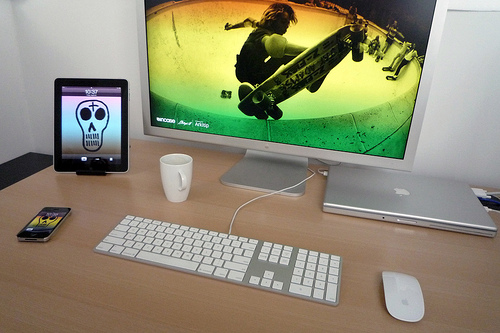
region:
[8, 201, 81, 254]
Phone on the desk.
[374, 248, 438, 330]
The mouse is white.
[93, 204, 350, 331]
The keys are white.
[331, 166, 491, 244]
The laptop is closed.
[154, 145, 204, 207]
Cup on the desk.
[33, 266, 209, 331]
The desk is brown.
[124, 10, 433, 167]
The monitor is on.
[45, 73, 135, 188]
Tablet on a stand.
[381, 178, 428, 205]
Apple logo on the laptop.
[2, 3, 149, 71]
The wall is white.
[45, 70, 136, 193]
An Apple iPad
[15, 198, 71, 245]
an iPhone with a drawing of a skull on the lock screen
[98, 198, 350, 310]
an Apple keyboard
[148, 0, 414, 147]
a man jumping a skateboard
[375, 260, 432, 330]
a white wireless Apple mouse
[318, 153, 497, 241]
a silver Apple laptop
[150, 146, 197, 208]
an empty white coffee cup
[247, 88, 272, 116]
the rubber wheel on a skateboard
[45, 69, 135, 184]
an iPad with a drawing of a skull on the locked screen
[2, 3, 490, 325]
a desk with several Apple products on it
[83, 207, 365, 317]
a white computer keyboard on a desk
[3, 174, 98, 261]
a cell phone on a desk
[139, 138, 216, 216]
a white coffee cup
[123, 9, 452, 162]
a silver computer monitor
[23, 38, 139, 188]
a computer tablet on a stand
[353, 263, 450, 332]
a white computer mouse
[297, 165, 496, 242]
a silver laptop on a desk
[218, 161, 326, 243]
a white cord attached to keyboard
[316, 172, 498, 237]
a closed laptop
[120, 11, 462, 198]
a computer monitor on a stand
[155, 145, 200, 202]
white ceramic coffee mug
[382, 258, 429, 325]
white computer mouse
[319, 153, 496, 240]
silver Apple laptop closed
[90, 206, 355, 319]
white and grey computer keyboard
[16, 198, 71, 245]
cell phone with skull on wallpaper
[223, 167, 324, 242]
keyboard cord snaking around monitor base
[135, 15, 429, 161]
computer monitor turned on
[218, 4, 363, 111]
skateboard graphic on monitor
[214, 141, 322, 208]
silver monitor base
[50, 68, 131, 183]
Ipad with skull on front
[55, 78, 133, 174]
Tablet on wooden table.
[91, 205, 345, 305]
Keyboard on wooden table.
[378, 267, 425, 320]
White computer mouse on wooden table.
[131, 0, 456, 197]
Computer monitor on wooden table.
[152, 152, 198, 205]
White coffee cup on wooden table.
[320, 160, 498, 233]
Silver colored laptop on wooden table.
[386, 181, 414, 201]
Apple logo on silver colored laptop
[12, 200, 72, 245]
Cell phone on wooden table.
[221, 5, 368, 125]
Person riding skateboard.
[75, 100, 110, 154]
Skull drawing on tablet.